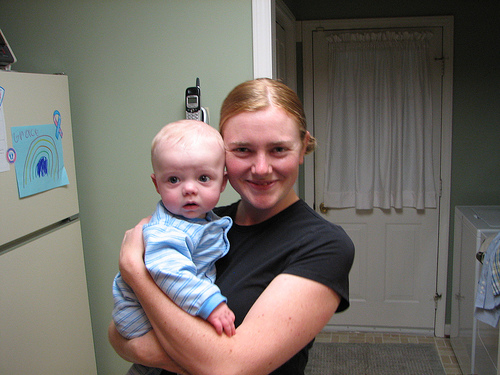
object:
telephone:
[184, 77, 202, 121]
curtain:
[323, 31, 438, 210]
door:
[311, 26, 441, 334]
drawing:
[9, 110, 69, 198]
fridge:
[1, 70, 97, 375]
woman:
[106, 77, 354, 375]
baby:
[110, 120, 234, 375]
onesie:
[113, 198, 233, 375]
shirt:
[165, 196, 354, 375]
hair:
[219, 77, 317, 155]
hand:
[119, 214, 152, 283]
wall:
[0, 2, 262, 373]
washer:
[450, 205, 500, 375]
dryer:
[449, 205, 500, 375]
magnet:
[6, 148, 16, 164]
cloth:
[473, 234, 500, 327]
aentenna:
[196, 77, 200, 88]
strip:
[252, 0, 275, 80]